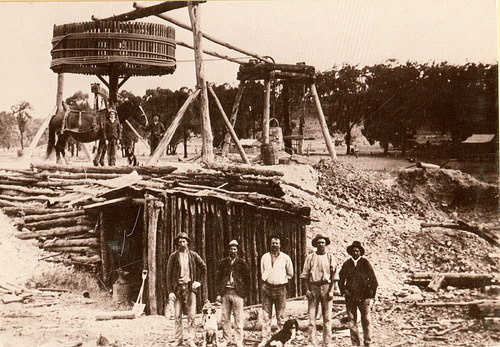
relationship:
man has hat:
[287, 228, 346, 336] [309, 235, 336, 246]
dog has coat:
[154, 288, 307, 346] [196, 301, 226, 339]